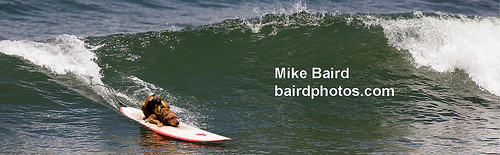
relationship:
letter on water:
[310, 67, 322, 82] [14, 9, 495, 154]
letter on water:
[323, 69, 330, 79] [14, 9, 495, 154]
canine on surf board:
[136, 86, 203, 153] [115, 96, 235, 147]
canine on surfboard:
[139, 94, 182, 127] [118, 93, 248, 144]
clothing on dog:
[140, 91, 155, 108] [130, 97, 199, 142]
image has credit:
[6, 2, 498, 151] [274, 67, 396, 100]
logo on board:
[191, 127, 219, 146] [119, 105, 234, 152]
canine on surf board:
[139, 94, 182, 127] [116, 102, 235, 153]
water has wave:
[173, 45, 243, 104] [3, 13, 496, 96]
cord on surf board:
[90, 73, 114, 93] [93, 71, 261, 153]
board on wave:
[118, 106, 234, 152] [6, 8, 498, 138]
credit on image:
[274, 67, 396, 100] [6, 2, 498, 151]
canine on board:
[139, 94, 182, 127] [118, 106, 234, 152]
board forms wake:
[118, 106, 234, 152] [33, 32, 102, 92]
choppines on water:
[6, 5, 498, 152] [11, 0, 487, 142]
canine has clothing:
[139, 94, 182, 127] [146, 94, 162, 115]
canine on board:
[139, 94, 182, 127] [160, 127, 229, 147]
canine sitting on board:
[139, 94, 182, 127] [116, 94, 232, 144]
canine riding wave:
[139, 94, 182, 127] [0, 10, 494, 125]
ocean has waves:
[6, 3, 496, 150] [311, 2, 496, 85]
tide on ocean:
[1, 1, 496, 56] [6, 3, 496, 150]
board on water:
[118, 106, 234, 152] [46, 57, 360, 152]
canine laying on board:
[139, 94, 182, 127] [117, 97, 232, 153]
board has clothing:
[118, 106, 234, 152] [146, 94, 162, 115]